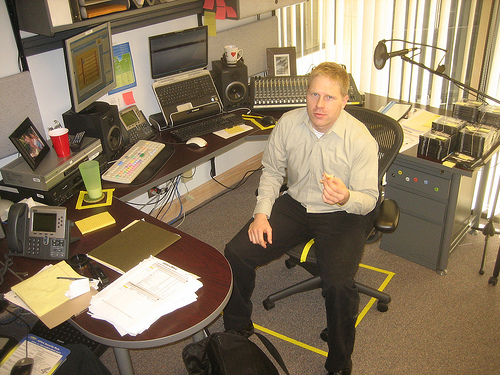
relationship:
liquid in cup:
[87, 187, 103, 200] [77, 161, 104, 200]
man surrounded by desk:
[225, 58, 381, 369] [2, 90, 498, 374]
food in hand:
[321, 173, 344, 185] [321, 173, 354, 207]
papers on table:
[88, 255, 204, 338] [2, 179, 235, 374]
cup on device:
[49, 128, 72, 160] [0, 131, 104, 193]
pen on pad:
[54, 276, 93, 280] [12, 260, 99, 329]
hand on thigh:
[249, 215, 276, 252] [229, 195, 314, 261]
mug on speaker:
[223, 46, 244, 68] [211, 60, 251, 111]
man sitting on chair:
[225, 58, 381, 369] [253, 104, 402, 341]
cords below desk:
[126, 157, 264, 233] [2, 90, 498, 374]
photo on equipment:
[9, 117, 52, 172] [0, 131, 104, 193]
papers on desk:
[88, 255, 204, 338] [2, 179, 235, 374]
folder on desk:
[84, 216, 180, 275] [2, 179, 235, 374]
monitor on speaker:
[62, 21, 118, 114] [62, 105, 126, 161]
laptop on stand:
[147, 26, 225, 128] [149, 113, 232, 130]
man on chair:
[225, 58, 381, 369] [253, 104, 402, 341]